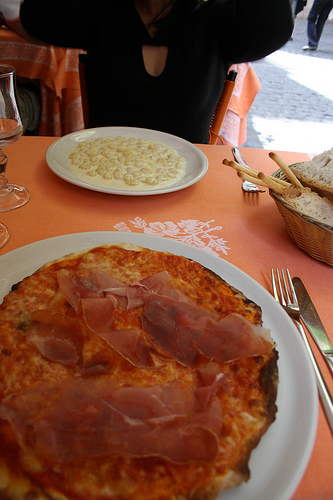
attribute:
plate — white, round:
[176, 133, 216, 186]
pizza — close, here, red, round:
[52, 255, 261, 475]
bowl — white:
[249, 293, 323, 413]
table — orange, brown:
[179, 194, 293, 268]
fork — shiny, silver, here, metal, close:
[260, 251, 305, 298]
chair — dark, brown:
[50, 29, 297, 152]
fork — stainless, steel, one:
[248, 240, 323, 399]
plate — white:
[6, 211, 203, 484]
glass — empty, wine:
[2, 62, 27, 240]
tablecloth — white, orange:
[55, 188, 288, 257]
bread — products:
[213, 130, 318, 209]